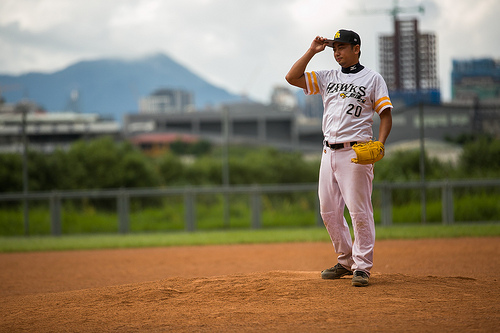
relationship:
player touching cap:
[278, 23, 403, 293] [299, 25, 363, 55]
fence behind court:
[2, 178, 314, 228] [1, 234, 499, 332]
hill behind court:
[0, 40, 252, 110] [1, 234, 499, 332]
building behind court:
[138, 86, 200, 115] [1, 234, 499, 332]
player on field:
[278, 23, 403, 293] [1, 234, 499, 332]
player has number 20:
[278, 23, 403, 293] [344, 101, 367, 119]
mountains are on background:
[0, 40, 252, 110] [0, 16, 295, 70]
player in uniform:
[278, 23, 403, 293] [301, 67, 397, 273]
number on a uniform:
[344, 101, 367, 119] [301, 67, 397, 273]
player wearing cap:
[278, 23, 403, 293] [322, 25, 364, 48]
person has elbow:
[278, 23, 403, 293] [280, 64, 307, 88]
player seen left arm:
[278, 23, 403, 293] [366, 73, 404, 162]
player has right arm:
[278, 23, 403, 293] [282, 31, 331, 102]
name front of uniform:
[323, 79, 369, 99] [301, 67, 397, 273]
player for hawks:
[278, 23, 403, 293] [323, 79, 369, 99]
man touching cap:
[278, 23, 403, 293] [322, 25, 364, 48]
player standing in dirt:
[278, 23, 403, 293] [1, 234, 499, 332]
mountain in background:
[0, 40, 252, 110] [0, 16, 295, 70]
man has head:
[278, 23, 403, 293] [311, 25, 375, 87]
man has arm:
[278, 23, 403, 293] [282, 31, 331, 102]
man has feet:
[278, 23, 403, 293] [316, 259, 375, 289]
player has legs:
[278, 23, 403, 293] [312, 174, 379, 291]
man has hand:
[278, 23, 403, 293] [307, 32, 329, 55]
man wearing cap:
[278, 23, 403, 293] [322, 25, 364, 48]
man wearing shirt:
[278, 23, 403, 293] [301, 61, 395, 144]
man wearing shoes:
[278, 23, 403, 293] [316, 259, 375, 289]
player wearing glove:
[278, 23, 403, 293] [349, 137, 388, 167]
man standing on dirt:
[278, 23, 403, 293] [1, 234, 499, 332]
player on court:
[278, 23, 403, 293] [5, 217, 493, 329]